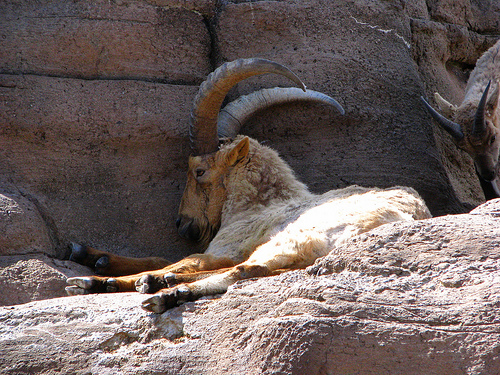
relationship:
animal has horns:
[64, 58, 431, 311] [190, 57, 343, 155]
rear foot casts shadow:
[141, 283, 191, 316] [152, 301, 195, 340]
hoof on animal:
[64, 276, 117, 296] [64, 58, 431, 311]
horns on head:
[190, 57, 343, 155] [176, 135, 296, 243]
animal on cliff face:
[64, 58, 431, 311] [0, 197, 499, 374]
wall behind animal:
[0, 0, 490, 263] [64, 58, 431, 311]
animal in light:
[64, 58, 431, 311] [0, 193, 499, 360]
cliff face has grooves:
[0, 197, 499, 374] [271, 309, 499, 341]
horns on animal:
[190, 57, 343, 155] [64, 58, 431, 311]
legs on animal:
[69, 242, 299, 314] [64, 58, 431, 311]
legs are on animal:
[69, 242, 299, 314] [64, 58, 431, 311]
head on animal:
[176, 135, 296, 243] [64, 58, 431, 311]